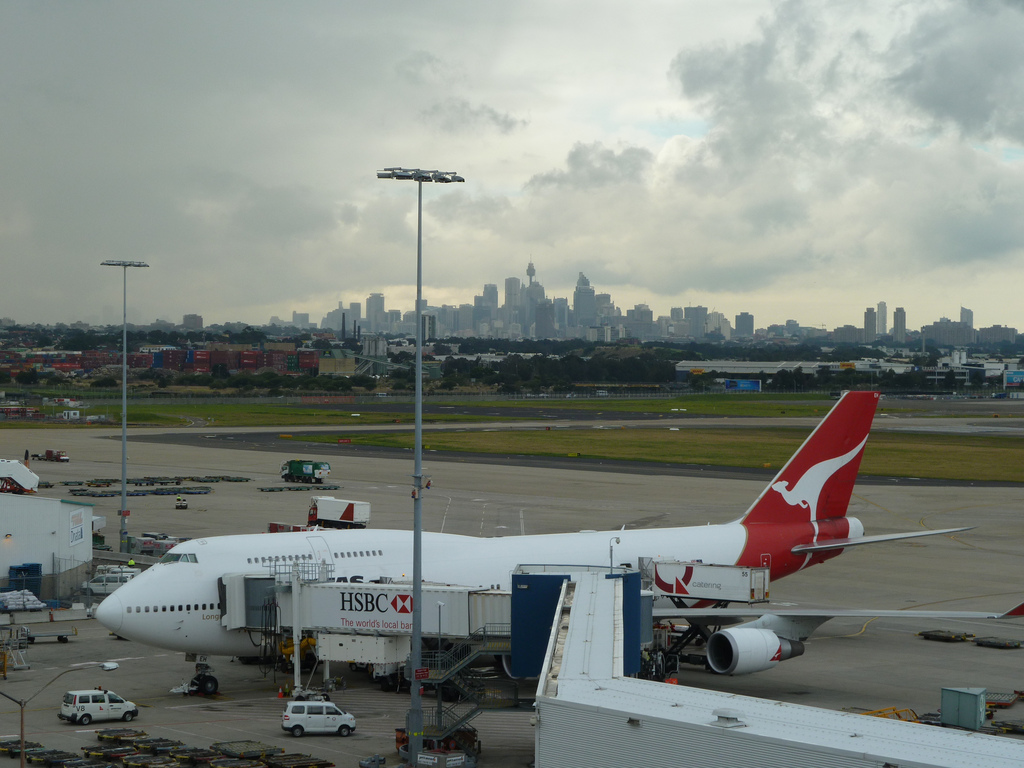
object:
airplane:
[96, 391, 1024, 675]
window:
[180, 554, 197, 562]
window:
[128, 606, 133, 613]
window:
[178, 605, 183, 611]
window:
[194, 604, 199, 610]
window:
[135, 607, 140, 614]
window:
[154, 606, 159, 612]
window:
[145, 606, 150, 613]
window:
[186, 604, 191, 611]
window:
[162, 606, 167, 612]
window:
[170, 605, 175, 611]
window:
[202, 604, 207, 610]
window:
[158, 553, 183, 562]